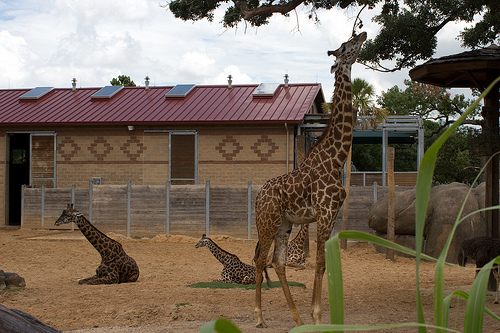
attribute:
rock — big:
[357, 158, 497, 284]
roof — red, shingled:
[0, 80, 334, 127]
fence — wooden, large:
[19, 183, 413, 230]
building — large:
[0, 77, 453, 250]